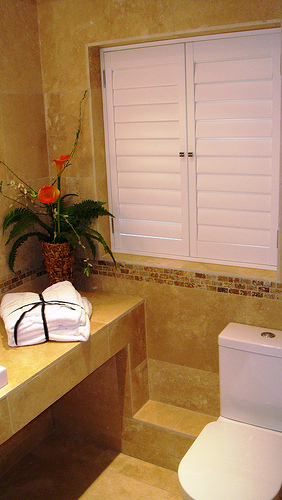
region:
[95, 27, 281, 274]
white window shutters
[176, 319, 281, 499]
white toilet on the wall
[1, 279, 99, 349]
white towel bundel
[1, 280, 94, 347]
black ribbon tied around towels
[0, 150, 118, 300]
flowers in a vase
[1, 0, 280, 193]
brown tiled wall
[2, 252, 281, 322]
mosaic on the brown tiled wall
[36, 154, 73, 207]
beautiful orange colored flower tops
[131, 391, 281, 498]
a step next to the toilet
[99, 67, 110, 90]
gray window hinge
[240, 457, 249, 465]
part of a toilet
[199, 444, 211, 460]
edge of a toilet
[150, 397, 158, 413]
part of the floor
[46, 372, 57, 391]
part of a table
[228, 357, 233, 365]
edge of a tank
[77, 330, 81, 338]
part of a towel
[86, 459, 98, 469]
part of a shadow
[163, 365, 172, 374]
side of a wall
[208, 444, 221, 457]
part of a toilet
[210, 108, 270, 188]
white shutters over the window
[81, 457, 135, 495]
yellow stone tiles of the bathroom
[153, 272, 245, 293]
small colored stone trim tiles on the wall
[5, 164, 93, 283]
orange flowers growing in a vase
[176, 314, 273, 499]
white porcelain toilet in the bathroom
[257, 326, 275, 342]
grey metal push button on top of the toilet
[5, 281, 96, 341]
white towels wrapped in a black ribbon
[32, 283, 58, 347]
black ribbon tied around a stack of towels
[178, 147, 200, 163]
brown metal handles of the shutters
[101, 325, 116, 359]
white grout lines between the tiles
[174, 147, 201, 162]
grey metal knobs on the window frame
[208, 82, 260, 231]
white wood shuuters over the windows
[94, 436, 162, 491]
tan stone tiles of the bathroom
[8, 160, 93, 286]
a green plant with orange flowers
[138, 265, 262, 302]
stone tile trim on the walls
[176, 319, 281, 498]
a white porcelain toilet in a bathroom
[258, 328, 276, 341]
grey metal push button on the toilet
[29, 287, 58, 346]
black ribbon wrapped around towels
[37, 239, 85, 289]
a stone planter in the corner of the counter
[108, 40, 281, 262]
the window is closed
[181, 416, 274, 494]
the toilet seat is white in colour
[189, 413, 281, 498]
the seat is closed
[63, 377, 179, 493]
the wall is brown in colour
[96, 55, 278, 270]
the window is white in colour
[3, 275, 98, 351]
a bundle of white clothes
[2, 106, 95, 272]
a flower in the vase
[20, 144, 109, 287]
the flowers are red in colour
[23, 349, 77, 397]
the wall is tiled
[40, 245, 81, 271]
the vase is marbled